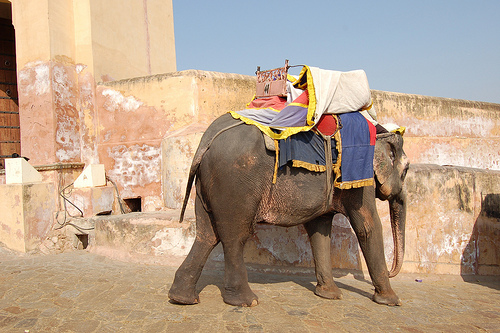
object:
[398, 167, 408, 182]
eye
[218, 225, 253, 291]
leg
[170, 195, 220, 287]
leg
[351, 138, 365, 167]
blue cloth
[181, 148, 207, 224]
elephant tail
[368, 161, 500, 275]
brick wall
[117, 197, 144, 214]
opening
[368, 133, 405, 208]
ear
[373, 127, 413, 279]
head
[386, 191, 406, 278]
trunk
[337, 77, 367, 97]
cloth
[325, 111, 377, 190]
blankets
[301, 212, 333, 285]
legs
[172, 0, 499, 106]
sky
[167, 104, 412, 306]
elephant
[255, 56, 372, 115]
seat